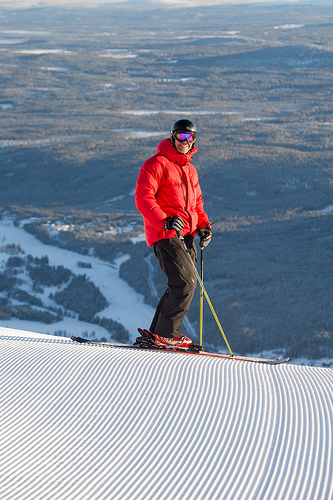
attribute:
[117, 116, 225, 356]
man — smiling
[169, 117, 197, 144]
helmet — ski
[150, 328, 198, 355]
ski boot — red, white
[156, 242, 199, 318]
pants — brown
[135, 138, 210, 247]
jacket — red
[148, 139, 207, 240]
jacket — for ski , man's